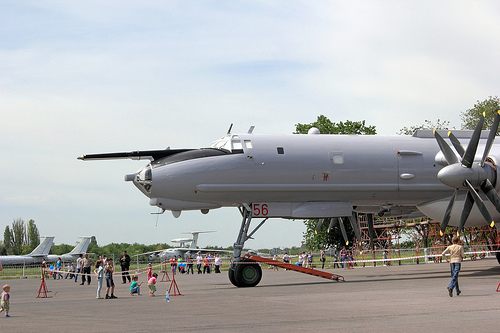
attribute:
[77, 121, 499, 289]
airplane — military, silver, parked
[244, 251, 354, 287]
ladder — red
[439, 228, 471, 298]
person — walking, looking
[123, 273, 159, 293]
chidren — crouching, looking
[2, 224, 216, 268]
planes — military, displayed, far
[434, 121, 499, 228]
propeller — yellow, gray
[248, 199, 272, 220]
numbers — red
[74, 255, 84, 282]
man — walking, running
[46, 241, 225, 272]
people — walking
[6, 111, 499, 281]
airplanes — displayed, grounded, militarys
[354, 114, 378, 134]
antenna — black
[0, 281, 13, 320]
baby — walking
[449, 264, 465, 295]
jeans — blue